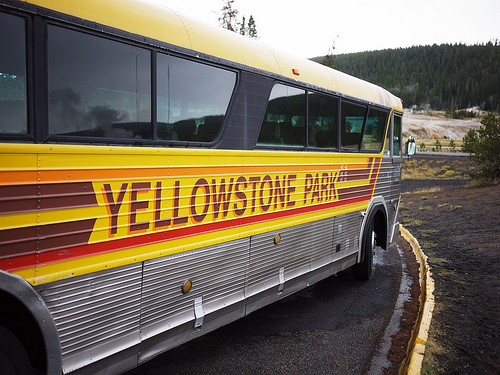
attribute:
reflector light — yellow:
[173, 271, 212, 301]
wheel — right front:
[350, 216, 387, 285]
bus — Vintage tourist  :
[0, 0, 414, 372]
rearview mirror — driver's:
[404, 133, 416, 160]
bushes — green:
[358, 39, 498, 101]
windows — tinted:
[7, 10, 397, 157]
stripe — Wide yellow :
[3, 134, 390, 291]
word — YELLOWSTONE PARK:
[102, 169, 297, 236]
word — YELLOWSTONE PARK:
[302, 170, 338, 203]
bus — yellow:
[54, 0, 419, 350]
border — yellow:
[395, 218, 434, 373]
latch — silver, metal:
[190, 288, 209, 338]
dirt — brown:
[414, 200, 499, 346]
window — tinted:
[151, 49, 241, 148]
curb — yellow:
[404, 246, 456, 371]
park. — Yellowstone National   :
[94, 157, 351, 235]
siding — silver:
[55, 222, 360, 358]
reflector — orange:
[177, 275, 200, 296]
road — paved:
[328, 288, 477, 353]